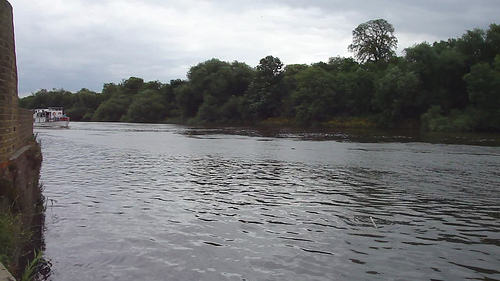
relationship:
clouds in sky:
[6, 1, 496, 98] [15, 0, 497, 99]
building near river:
[23, 105, 65, 123] [42, 118, 482, 279]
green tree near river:
[347, 17, 397, 69] [42, 118, 482, 279]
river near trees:
[33, 121, 499, 281] [365, 63, 405, 124]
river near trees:
[33, 121, 499, 281] [287, 66, 344, 131]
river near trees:
[33, 121, 499, 281] [243, 53, 290, 126]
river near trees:
[33, 121, 499, 281] [192, 65, 242, 129]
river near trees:
[33, 121, 499, 281] [461, 58, 497, 132]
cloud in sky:
[45, 43, 118, 73] [77, 4, 342, 53]